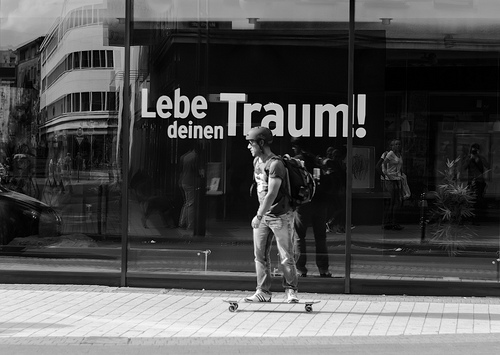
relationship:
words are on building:
[139, 87, 366, 139] [0, 1, 499, 300]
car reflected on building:
[2, 181, 64, 251] [0, 1, 499, 300]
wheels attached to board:
[225, 302, 314, 317] [218, 293, 322, 313]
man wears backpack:
[237, 122, 310, 305] [282, 154, 319, 211]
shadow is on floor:
[0, 315, 72, 334] [0, 277, 500, 354]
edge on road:
[2, 282, 499, 308] [1, 285, 498, 353]